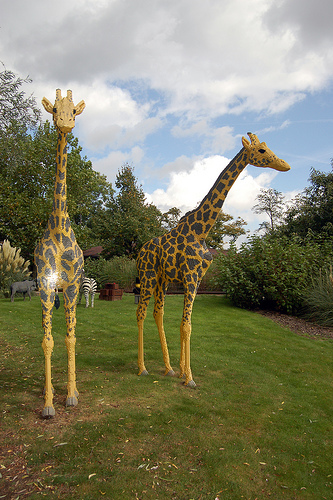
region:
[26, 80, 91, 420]
giraffe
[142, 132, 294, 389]
giraffe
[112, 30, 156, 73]
white clouds in blue sky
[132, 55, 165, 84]
white clouds in blue sky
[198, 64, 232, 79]
white clouds in blue sky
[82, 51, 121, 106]
white clouds in blue sky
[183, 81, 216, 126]
white clouds in blue sky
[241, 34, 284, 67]
white clouds in blue sky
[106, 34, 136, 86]
white clouds in blue sky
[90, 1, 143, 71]
white clouds in blue sky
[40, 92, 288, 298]
two large lego giraffes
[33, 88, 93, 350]
large lego giraffe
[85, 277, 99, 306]
butt of a lego zebra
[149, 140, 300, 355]
lego giraffe in the grass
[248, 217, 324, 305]
multiple green bushes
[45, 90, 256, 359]
many lego African animals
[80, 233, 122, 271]
small building behind trees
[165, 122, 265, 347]
large lego spotted giraffe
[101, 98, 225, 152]
white fluffy clouds in the sky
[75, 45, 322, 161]
blue sky and white clouds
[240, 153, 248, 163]
brown spot on giraffe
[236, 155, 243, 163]
brown spot on giraffe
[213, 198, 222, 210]
brown spot on giraffe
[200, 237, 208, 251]
brown spot on giraffe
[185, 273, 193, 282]
brown spot on giraffe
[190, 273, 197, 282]
brown spot on giraffe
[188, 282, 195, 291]
brown spot on giraffe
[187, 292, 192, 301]
brown spot on giraffe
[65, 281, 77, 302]
brown spot on giraffe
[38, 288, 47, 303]
brown spot on giraffe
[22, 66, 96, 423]
The giraffe is gray and yellow.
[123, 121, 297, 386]
The giraffe is gray and yellow.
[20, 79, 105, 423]
The giraffe is not real.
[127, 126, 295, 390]
The giraffe is not real.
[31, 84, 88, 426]
The giraffe is a statue.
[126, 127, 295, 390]
The giraffe is a statue.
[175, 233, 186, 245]
The spot is gray.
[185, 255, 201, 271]
The spot is gray.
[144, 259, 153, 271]
The spot is gray.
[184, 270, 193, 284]
The spot is gray.